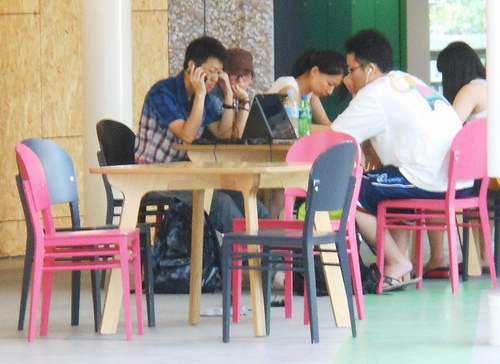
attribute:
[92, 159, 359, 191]
table — wooden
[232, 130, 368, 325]
chair — pink, empty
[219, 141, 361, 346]
chair — empty, blue, gray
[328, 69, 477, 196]
shirt — white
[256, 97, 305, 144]
laptop — open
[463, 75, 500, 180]
shirt — white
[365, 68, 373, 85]
earbuds — white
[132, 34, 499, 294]
people — studying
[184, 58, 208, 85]
cell phone — black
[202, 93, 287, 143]
laptop — open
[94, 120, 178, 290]
chair — metal, black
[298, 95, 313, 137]
bottle — green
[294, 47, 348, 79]
hair — long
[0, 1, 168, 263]
wall — plywood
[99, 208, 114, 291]
leg — metal